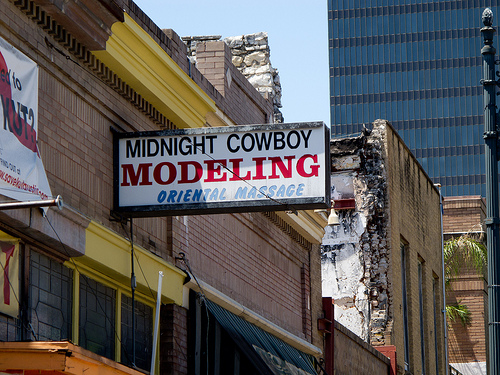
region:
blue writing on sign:
[157, 187, 229, 202]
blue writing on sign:
[232, 185, 302, 200]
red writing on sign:
[118, 153, 326, 183]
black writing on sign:
[122, 127, 319, 159]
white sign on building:
[0, 33, 54, 202]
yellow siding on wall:
[89, 8, 237, 127]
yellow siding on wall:
[68, 217, 193, 308]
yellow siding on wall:
[270, 211, 335, 241]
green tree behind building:
[441, 235, 482, 272]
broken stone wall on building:
[349, 125, 382, 348]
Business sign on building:
[112, 121, 332, 210]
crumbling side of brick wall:
[326, 114, 396, 350]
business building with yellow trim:
[75, 5, 191, 373]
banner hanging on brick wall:
[0, 34, 59, 216]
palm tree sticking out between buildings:
[442, 215, 488, 327]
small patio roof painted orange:
[0, 331, 149, 373]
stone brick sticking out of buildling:
[182, 26, 282, 98]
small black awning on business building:
[194, 289, 324, 374]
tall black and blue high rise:
[326, 1, 498, 191]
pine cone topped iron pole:
[480, 3, 498, 374]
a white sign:
[117, 130, 322, 206]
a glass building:
[327, 1, 479, 192]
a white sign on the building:
[5, 51, 55, 206]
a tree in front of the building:
[445, 226, 478, 281]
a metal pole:
[479, 8, 499, 364]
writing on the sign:
[122, 140, 297, 182]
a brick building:
[443, 196, 492, 357]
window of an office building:
[335, 66, 346, 91]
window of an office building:
[357, 65, 379, 103]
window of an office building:
[387, 65, 398, 106]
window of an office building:
[410, 65, 425, 96]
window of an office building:
[435, 65, 457, 90]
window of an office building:
[469, 86, 481, 117]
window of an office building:
[445, 92, 466, 119]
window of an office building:
[425, 88, 446, 118]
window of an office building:
[422, 91, 436, 113]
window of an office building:
[430, 136, 450, 176]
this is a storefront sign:
[89, 95, 344, 230]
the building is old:
[317, 85, 419, 350]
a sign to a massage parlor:
[84, 71, 339, 237]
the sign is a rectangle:
[110, 81, 377, 235]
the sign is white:
[83, 93, 375, 225]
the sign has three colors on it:
[88, 95, 352, 238]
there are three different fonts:
[106, 112, 342, 260]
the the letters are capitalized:
[85, 99, 338, 226]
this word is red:
[113, 153, 328, 187]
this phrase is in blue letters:
[141, 182, 314, 209]